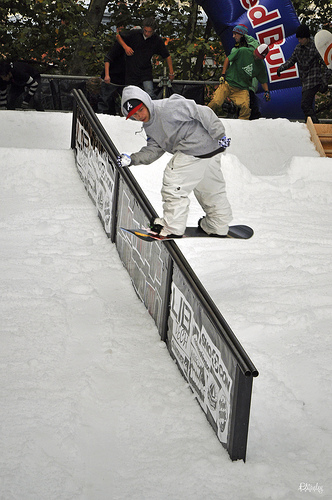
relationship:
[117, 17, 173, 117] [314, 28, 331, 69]
person in snowboard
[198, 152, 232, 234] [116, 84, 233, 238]
leg of man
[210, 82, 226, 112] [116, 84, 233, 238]
leg of man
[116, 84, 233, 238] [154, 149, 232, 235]
man wearing pants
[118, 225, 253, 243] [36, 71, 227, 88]
snowboard on rail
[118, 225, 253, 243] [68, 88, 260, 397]
snowboard on rail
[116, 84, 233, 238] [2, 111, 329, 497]
man above snow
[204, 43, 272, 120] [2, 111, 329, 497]
person above snow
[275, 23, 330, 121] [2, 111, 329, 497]
person above snow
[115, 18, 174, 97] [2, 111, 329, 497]
person above snow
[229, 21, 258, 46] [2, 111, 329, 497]
person above snow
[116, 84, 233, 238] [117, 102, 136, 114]
man wearing hat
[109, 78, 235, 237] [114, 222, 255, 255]
man on snowboard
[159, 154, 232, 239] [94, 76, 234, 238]
pants on man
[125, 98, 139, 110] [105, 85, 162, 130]
hat on head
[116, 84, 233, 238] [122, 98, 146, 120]
man wearing hat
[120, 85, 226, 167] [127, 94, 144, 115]
jacket over hat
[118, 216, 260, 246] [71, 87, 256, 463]
snowboard on ramp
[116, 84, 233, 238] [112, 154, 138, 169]
man has hand